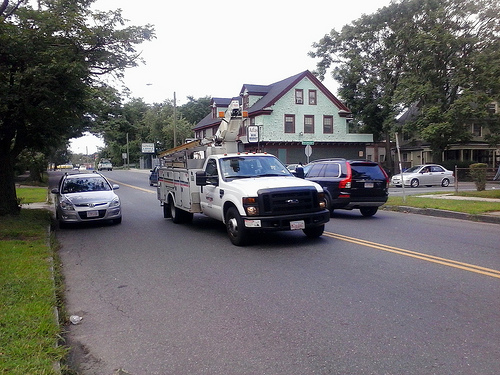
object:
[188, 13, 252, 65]
sky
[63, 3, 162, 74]
tree branches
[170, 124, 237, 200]
sign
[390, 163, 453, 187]
car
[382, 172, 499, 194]
road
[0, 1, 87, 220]
tree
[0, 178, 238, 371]
roadside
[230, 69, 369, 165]
house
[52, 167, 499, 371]
street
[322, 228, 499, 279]
line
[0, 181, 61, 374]
grass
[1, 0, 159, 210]
tree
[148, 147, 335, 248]
truck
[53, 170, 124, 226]
car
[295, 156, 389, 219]
suv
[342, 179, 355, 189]
tail light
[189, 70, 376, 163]
house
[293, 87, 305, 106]
window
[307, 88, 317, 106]
window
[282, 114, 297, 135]
window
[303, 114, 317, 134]
window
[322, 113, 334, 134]
window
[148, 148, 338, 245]
utility truck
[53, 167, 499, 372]
road